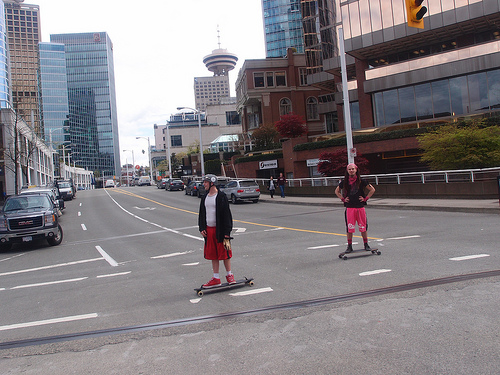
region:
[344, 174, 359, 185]
Guy has on pink scarf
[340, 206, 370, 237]
Guy has on pink and black shorts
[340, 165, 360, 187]
Guy's hair is long and twisted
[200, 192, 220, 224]
Guy has on white tank top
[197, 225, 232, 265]
Guy has on red shorts with black stripe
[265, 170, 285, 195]
Couple walking hand in hand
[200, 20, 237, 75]
Tall building with a satelite needle on top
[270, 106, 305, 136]
Tree with red leaves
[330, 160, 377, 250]
Guy has hands on his hips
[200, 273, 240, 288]
Guy has on red shoes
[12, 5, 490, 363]
Phot taken during the day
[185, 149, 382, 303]
Two people on skateboards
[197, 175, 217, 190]
Helmet on the man's head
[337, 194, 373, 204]
Sweatbands on the wrists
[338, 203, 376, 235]
Pink shorts on the man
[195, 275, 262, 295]
The skateboard is a long board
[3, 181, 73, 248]
Truck parked near the sidewalk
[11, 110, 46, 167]
No leaves on the tree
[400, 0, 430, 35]
Yellow traffic light over head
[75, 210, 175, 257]
White lines on the road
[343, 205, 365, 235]
pink and black shorts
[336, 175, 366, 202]
black cotton tee shirt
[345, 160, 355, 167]
pink bandana on head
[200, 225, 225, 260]
red and black shorts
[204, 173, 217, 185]
black and white helmet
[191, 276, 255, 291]
black skateboard on road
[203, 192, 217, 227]
white cotton tee shirt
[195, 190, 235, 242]
black sweat shirt jacket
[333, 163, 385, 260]
man standing on skate board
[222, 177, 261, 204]
grey car on road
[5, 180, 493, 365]
gray paved street with white and yellow lines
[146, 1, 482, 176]
tall and short buildings on side of street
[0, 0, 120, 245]
short buildings and skyscrapers behind cars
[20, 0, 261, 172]
bright sky over city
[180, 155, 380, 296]
two skateboarders crossing the street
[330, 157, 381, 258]
skateboarder with hands at waist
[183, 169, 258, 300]
skateboarder in baggy clothes looking forward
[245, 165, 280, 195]
two people walking past car on sidewalk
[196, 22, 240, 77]
pole on top of round building with dark rings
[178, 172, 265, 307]
male skateboarder in the street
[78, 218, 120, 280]
white lines painted on the road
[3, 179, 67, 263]
car parked along side of road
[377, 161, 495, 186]
fence in the grass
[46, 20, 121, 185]
building in the distance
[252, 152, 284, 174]
sign on a building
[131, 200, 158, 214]
painted arrow in the road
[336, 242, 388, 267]
skateboard on the street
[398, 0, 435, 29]
traffic light above road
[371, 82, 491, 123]
windows on a building